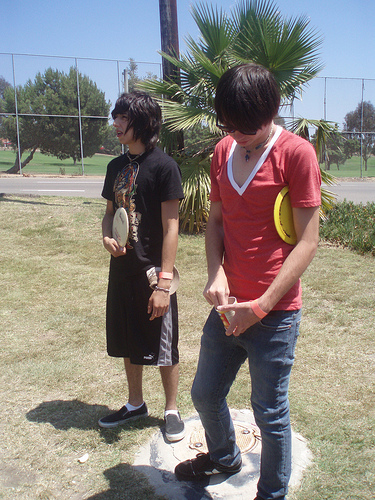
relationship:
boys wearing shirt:
[175, 62, 322, 499] [201, 133, 325, 318]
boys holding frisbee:
[175, 62, 322, 499] [274, 185, 299, 249]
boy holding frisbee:
[100, 79, 188, 454] [111, 205, 130, 260]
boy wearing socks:
[100, 79, 188, 454] [123, 402, 180, 418]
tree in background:
[137, 8, 326, 261] [1, 6, 370, 258]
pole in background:
[157, 1, 190, 171] [1, 6, 370, 258]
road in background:
[2, 172, 117, 206] [1, 6, 370, 258]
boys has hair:
[175, 62, 322, 499] [215, 62, 282, 132]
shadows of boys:
[27, 391, 210, 499] [94, 59, 329, 499]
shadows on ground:
[27, 391, 210, 499] [3, 193, 374, 498]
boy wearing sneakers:
[100, 79, 188, 454] [101, 407, 187, 443]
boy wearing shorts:
[100, 79, 188, 454] [98, 247, 181, 371]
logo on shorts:
[137, 346, 158, 364] [98, 247, 181, 371]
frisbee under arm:
[274, 185, 299, 249] [239, 148, 327, 352]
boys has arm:
[175, 62, 322, 499] [239, 148, 327, 352]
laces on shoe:
[185, 450, 211, 471] [173, 452, 240, 483]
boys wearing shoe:
[175, 62, 322, 499] [173, 452, 240, 483]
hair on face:
[120, 112, 134, 139] [112, 112, 134, 146]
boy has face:
[100, 79, 188, 454] [112, 112, 134, 146]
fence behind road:
[3, 49, 374, 189] [2, 172, 117, 206]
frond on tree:
[242, 8, 288, 74] [137, 8, 326, 261]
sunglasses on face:
[214, 119, 264, 137] [220, 110, 264, 150]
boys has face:
[175, 62, 322, 499] [220, 110, 264, 150]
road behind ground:
[2, 172, 117, 206] [3, 193, 374, 498]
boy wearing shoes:
[100, 79, 188, 454] [101, 407, 187, 443]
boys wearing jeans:
[175, 62, 322, 499] [192, 298, 305, 500]